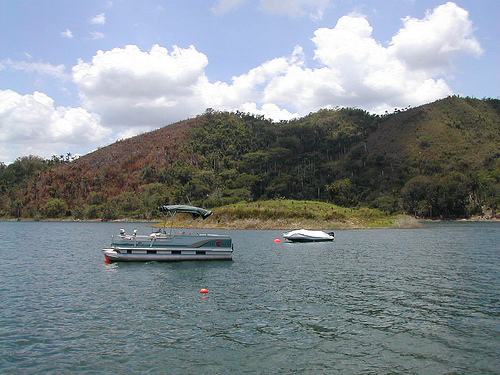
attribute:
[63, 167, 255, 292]
boat — floating, green, white, large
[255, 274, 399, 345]
water — calm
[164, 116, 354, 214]
trees — green, growing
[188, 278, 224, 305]
floater — pink, orange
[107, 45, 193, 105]
cloud — white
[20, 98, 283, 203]
hills — rising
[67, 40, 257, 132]
clouds — white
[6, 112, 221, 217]
buoy — orange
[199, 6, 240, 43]
sky — blue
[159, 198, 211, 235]
canvas — green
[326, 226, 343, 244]
motor — black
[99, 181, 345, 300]
pontoons — supporting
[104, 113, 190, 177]
vegetation — brown